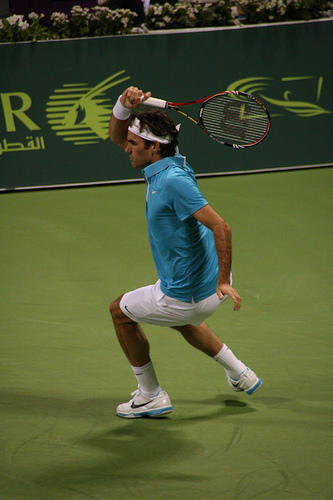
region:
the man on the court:
[83, 81, 285, 431]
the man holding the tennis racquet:
[100, 64, 289, 436]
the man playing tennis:
[75, 74, 304, 423]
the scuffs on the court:
[217, 417, 295, 498]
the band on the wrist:
[99, 91, 139, 126]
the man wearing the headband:
[107, 103, 275, 444]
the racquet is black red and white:
[126, 82, 277, 156]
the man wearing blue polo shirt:
[124, 157, 232, 293]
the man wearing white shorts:
[110, 272, 230, 344]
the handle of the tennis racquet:
[131, 94, 164, 105]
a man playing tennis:
[102, 74, 206, 199]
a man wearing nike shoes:
[102, 334, 287, 453]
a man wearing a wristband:
[97, 54, 187, 148]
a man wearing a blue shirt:
[114, 87, 252, 349]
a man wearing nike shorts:
[94, 239, 277, 380]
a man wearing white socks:
[102, 299, 289, 419]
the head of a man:
[112, 74, 219, 209]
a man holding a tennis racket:
[89, 7, 260, 190]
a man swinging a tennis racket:
[83, 65, 321, 237]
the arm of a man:
[149, 156, 285, 343]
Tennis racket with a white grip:
[117, 87, 273, 149]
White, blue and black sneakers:
[112, 366, 263, 417]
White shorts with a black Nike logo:
[119, 278, 234, 326]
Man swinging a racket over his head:
[106, 84, 271, 421]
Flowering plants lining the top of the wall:
[0, 0, 332, 44]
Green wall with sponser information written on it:
[1, 17, 332, 194]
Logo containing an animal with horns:
[45, 68, 130, 146]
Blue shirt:
[141, 154, 230, 300]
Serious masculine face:
[124, 128, 150, 169]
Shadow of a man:
[75, 397, 259, 484]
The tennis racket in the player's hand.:
[137, 93, 273, 144]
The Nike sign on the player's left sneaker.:
[131, 400, 151, 406]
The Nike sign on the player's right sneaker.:
[230, 383, 239, 387]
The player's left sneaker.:
[115, 391, 173, 419]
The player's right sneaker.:
[222, 365, 258, 393]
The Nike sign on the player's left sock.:
[134, 369, 142, 375]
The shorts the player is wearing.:
[120, 279, 225, 329]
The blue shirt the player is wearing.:
[139, 161, 227, 298]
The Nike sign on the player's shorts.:
[123, 303, 134, 315]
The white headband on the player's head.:
[131, 117, 179, 142]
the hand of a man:
[113, 74, 164, 107]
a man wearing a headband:
[115, 88, 212, 185]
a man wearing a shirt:
[96, 146, 254, 336]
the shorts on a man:
[100, 247, 272, 372]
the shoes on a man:
[98, 342, 288, 434]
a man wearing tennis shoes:
[84, 314, 304, 461]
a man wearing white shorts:
[103, 294, 280, 430]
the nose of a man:
[112, 130, 152, 172]